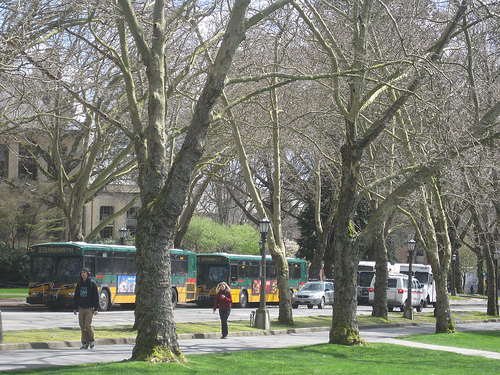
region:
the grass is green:
[283, 346, 397, 367]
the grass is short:
[294, 337, 384, 373]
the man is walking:
[67, 248, 119, 350]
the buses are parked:
[37, 225, 332, 310]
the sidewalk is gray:
[210, 334, 310, 356]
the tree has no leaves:
[110, 37, 235, 348]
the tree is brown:
[86, 27, 223, 362]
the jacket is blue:
[61, 267, 113, 312]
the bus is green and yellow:
[11, 223, 221, 323]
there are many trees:
[135, 77, 458, 338]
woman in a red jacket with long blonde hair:
[205, 272, 242, 336]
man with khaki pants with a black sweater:
[55, 263, 108, 348]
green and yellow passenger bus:
[12, 217, 201, 311]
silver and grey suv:
[290, 273, 342, 310]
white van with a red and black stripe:
[365, 266, 427, 315]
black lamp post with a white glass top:
[250, 206, 278, 335]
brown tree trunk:
[127, 198, 192, 370]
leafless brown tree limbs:
[10, 0, 497, 177]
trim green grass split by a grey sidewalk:
[378, 327, 498, 373]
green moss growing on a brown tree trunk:
[131, 346, 185, 363]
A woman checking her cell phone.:
[207, 276, 238, 341]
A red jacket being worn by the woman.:
[204, 288, 239, 318]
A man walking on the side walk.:
[66, 263, 105, 351]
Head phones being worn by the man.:
[74, 264, 94, 283]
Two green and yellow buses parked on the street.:
[30, 244, 308, 309]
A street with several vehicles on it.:
[0, 267, 498, 340]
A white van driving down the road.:
[359, 267, 433, 318]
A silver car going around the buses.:
[276, 271, 341, 325]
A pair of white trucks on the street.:
[328, 256, 444, 316]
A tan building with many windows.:
[3, 128, 167, 258]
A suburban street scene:
[30, 17, 467, 359]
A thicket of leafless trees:
[27, 55, 482, 210]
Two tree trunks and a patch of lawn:
[128, 321, 363, 371]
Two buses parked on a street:
[28, 243, 307, 305]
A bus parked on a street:
[29, 246, 202, 305]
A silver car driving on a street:
[290, 279, 333, 314]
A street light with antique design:
[249, 213, 275, 330]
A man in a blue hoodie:
[71, 263, 99, 353]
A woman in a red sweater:
[209, 281, 234, 343]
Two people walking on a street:
[56, 265, 237, 345]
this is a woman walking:
[213, 278, 234, 335]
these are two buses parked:
[175, 258, 242, 277]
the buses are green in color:
[179, 256, 244, 277]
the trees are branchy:
[0, 0, 498, 188]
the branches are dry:
[10, 4, 497, 196]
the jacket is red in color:
[220, 294, 227, 305]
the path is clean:
[246, 332, 313, 343]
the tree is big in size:
[316, 152, 384, 322]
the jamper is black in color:
[80, 281, 92, 303]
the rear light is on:
[396, 288, 404, 291]